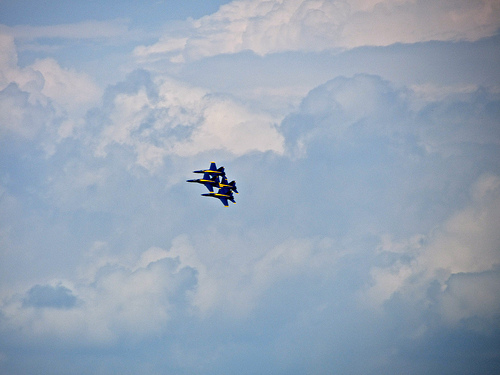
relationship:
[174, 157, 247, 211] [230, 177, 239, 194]
planes has tail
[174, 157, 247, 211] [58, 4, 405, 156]
planes in sky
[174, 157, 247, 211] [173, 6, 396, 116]
planes in clouds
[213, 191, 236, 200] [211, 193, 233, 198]
fuselage has stripe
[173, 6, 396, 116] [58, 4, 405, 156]
clouds in sky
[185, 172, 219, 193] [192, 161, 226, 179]
airplane behind planes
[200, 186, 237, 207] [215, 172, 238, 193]
airplane behind airplane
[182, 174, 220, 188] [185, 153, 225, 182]
airplane under airplane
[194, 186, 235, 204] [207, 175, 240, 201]
airplane under airplane